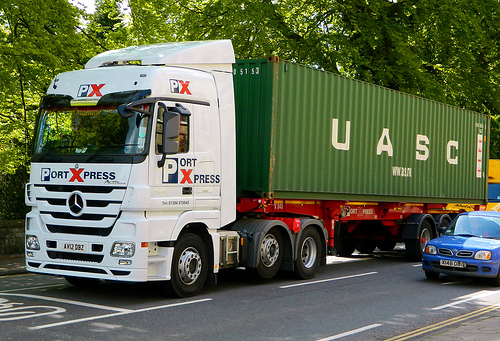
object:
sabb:
[416, 205, 496, 284]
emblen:
[65, 189, 88, 218]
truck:
[23, 44, 493, 296]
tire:
[406, 219, 436, 262]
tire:
[293, 223, 326, 279]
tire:
[252, 226, 287, 280]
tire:
[169, 234, 211, 299]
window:
[32, 103, 149, 158]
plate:
[56, 241, 88, 252]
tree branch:
[417, 0, 500, 96]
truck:
[15, 47, 484, 279]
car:
[419, 210, 498, 284]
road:
[0, 261, 495, 337]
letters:
[79, 83, 101, 98]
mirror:
[161, 110, 182, 154]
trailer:
[274, 50, 498, 208]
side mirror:
[160, 107, 182, 159]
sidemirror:
[148, 107, 195, 152]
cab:
[24, 34, 237, 298]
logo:
[329, 118, 354, 151]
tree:
[7, 5, 81, 189]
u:
[329, 115, 354, 152]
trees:
[0, 0, 499, 256]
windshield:
[30, 92, 190, 161]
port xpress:
[157, 156, 220, 187]